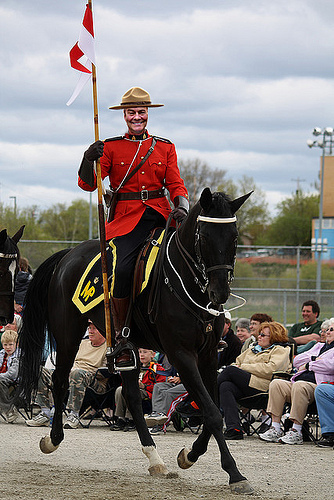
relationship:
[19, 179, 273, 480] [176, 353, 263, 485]
horse has leg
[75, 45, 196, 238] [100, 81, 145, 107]
man with hat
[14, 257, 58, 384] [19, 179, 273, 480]
tail on horse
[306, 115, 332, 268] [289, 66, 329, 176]
building has light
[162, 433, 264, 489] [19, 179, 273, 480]
hoof of horse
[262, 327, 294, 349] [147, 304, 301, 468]
sunglasses on woman